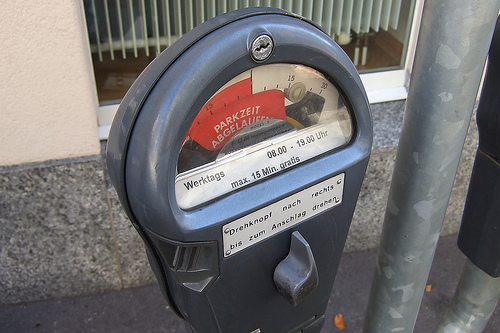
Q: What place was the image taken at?
A: It was taken at the sidewalk.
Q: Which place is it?
A: It is a sidewalk.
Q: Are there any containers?
A: No, there are no containers.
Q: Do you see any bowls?
A: No, there are no bowls.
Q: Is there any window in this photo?
A: Yes, there is a window.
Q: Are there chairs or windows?
A: Yes, there is a window.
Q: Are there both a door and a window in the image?
A: No, there is a window but no doors.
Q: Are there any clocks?
A: No, there are no clocks.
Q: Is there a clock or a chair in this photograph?
A: No, there are no clocks or chairs.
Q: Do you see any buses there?
A: No, there are no buses.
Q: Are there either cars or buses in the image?
A: No, there are no buses or cars.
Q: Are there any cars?
A: No, there are no cars.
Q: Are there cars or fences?
A: No, there are no cars or fences.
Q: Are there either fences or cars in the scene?
A: No, there are no cars or fences.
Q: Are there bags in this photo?
A: No, there are no bags.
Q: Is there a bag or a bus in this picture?
A: No, there are no bags or buses.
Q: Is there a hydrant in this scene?
A: No, there are no fire hydrants.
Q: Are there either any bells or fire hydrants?
A: No, there are no fire hydrants or bells.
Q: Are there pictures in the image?
A: No, there are no pictures.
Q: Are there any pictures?
A: No, there are no pictures.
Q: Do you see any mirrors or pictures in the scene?
A: No, there are no pictures or mirrors.